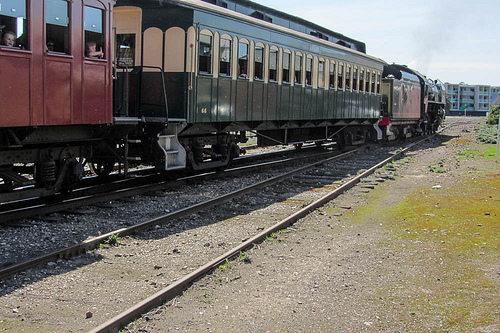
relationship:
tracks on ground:
[97, 199, 226, 273] [230, 262, 303, 298]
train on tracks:
[200, 26, 339, 135] [97, 199, 226, 273]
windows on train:
[224, 37, 327, 68] [200, 26, 339, 135]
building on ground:
[446, 90, 483, 112] [230, 262, 303, 298]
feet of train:
[273, 130, 297, 149] [200, 26, 339, 135]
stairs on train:
[154, 143, 182, 169] [200, 26, 339, 135]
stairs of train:
[154, 143, 182, 169] [200, 26, 339, 135]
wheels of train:
[31, 138, 101, 195] [200, 26, 339, 135]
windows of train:
[224, 37, 327, 68] [200, 26, 339, 135]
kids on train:
[0, 28, 95, 52] [200, 26, 339, 135]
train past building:
[200, 26, 339, 135] [446, 90, 483, 112]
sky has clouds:
[386, 13, 448, 42] [437, 45, 472, 66]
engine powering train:
[382, 60, 442, 139] [1, 0, 449, 205]